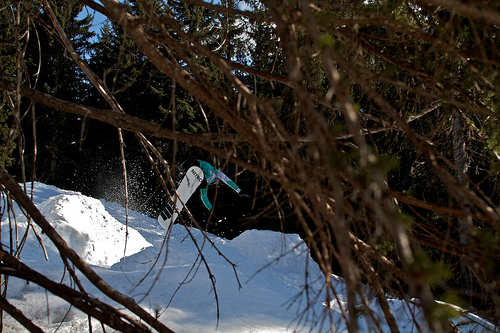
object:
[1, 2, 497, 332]
tree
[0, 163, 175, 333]
branch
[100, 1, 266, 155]
branch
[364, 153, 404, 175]
leaf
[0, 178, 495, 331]
snow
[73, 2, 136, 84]
sky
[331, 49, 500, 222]
branch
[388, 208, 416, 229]
leaf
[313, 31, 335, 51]
leaf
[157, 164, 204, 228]
snowboard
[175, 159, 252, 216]
snowboarder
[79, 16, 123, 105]
pine tree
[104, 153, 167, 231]
snow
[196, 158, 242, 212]
suit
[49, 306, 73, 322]
hole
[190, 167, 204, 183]
logo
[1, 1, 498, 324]
forest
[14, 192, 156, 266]
jump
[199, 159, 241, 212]
jacket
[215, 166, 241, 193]
arm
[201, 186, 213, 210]
arm